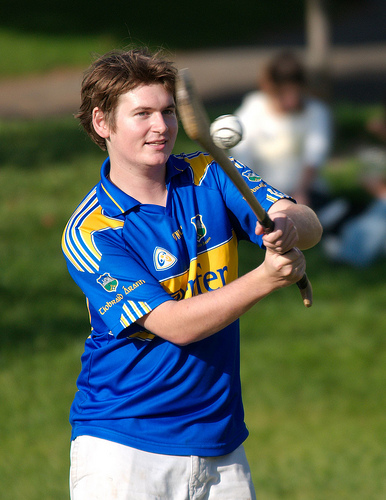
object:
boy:
[60, 44, 324, 500]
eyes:
[134, 109, 152, 119]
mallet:
[174, 67, 313, 307]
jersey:
[61, 151, 297, 456]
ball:
[209, 113, 243, 149]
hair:
[71, 35, 189, 152]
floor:
[96, 177, 140, 217]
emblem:
[96, 272, 119, 292]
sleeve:
[60, 231, 175, 340]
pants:
[70, 435, 255, 498]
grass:
[0, 25, 381, 498]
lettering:
[169, 263, 227, 301]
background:
[159, 230, 238, 299]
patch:
[96, 272, 118, 292]